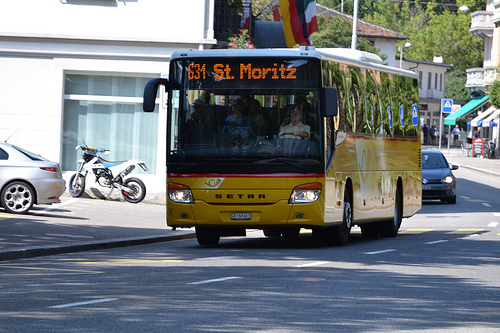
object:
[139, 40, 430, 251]
bus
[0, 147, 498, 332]
road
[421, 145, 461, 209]
car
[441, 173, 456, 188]
headlight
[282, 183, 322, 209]
headlight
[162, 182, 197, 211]
headlight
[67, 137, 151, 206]
motorcycle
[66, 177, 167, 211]
sidewalk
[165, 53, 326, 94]
marquee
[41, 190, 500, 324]
line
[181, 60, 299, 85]
destination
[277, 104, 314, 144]
bus driver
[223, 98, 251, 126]
passenger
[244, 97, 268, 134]
passenger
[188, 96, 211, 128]
passenger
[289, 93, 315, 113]
passenger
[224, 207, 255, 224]
license plate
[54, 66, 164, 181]
window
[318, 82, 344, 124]
side view mirror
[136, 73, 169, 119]
side view mirror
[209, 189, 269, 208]
bus company name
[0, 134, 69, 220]
car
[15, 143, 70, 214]
back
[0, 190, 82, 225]
lot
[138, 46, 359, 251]
front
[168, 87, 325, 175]
windshield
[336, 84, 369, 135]
window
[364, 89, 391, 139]
window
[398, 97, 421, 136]
window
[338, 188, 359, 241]
wheel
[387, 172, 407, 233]
wheel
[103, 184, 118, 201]
kickstand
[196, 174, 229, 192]
decal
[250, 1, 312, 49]
flag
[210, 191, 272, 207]
logo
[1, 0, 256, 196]
building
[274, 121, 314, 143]
shirt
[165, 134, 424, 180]
stripe